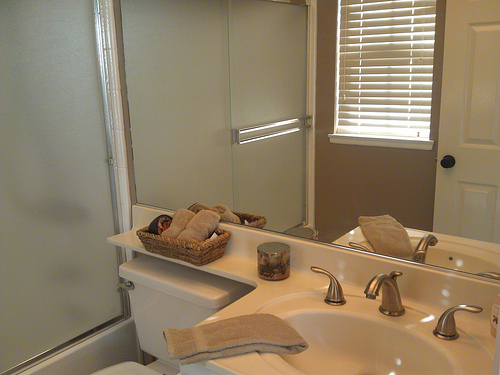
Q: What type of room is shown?
A: It is a bathroom.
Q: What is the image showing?
A: It is showing a bathroom.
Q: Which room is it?
A: It is a bathroom.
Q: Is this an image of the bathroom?
A: Yes, it is showing the bathroom.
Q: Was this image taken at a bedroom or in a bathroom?
A: It was taken at a bathroom.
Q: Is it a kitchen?
A: No, it is a bathroom.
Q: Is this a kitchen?
A: No, it is a bathroom.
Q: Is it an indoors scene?
A: Yes, it is indoors.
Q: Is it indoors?
A: Yes, it is indoors.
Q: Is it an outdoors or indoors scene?
A: It is indoors.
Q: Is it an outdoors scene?
A: No, it is indoors.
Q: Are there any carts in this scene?
A: No, there are no carts.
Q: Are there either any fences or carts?
A: No, there are no carts or fences.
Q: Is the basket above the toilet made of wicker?
A: Yes, the basket is made of wicker.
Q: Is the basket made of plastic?
A: No, the basket is made of wicker.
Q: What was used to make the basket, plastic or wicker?
A: The basket is made of wicker.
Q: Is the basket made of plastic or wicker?
A: The basket is made of wicker.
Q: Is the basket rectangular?
A: Yes, the basket is rectangular.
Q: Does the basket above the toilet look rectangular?
A: Yes, the basket is rectangular.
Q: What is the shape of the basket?
A: The basket is rectangular.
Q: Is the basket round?
A: No, the basket is rectangular.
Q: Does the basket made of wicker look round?
A: No, the basket is rectangular.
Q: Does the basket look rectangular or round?
A: The basket is rectangular.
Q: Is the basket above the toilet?
A: Yes, the basket is above the toilet.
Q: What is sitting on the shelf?
A: The basket is sitting on the shelf.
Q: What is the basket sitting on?
A: The basket is sitting on the shelf.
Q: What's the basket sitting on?
A: The basket is sitting on the shelf.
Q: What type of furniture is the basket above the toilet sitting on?
A: The basket is sitting on the shelf.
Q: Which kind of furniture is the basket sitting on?
A: The basket is sitting on the shelf.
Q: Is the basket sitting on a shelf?
A: Yes, the basket is sitting on a shelf.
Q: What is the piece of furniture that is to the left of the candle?
A: The piece of furniture is a shelf.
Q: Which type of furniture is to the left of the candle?
A: The piece of furniture is a shelf.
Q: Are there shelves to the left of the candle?
A: Yes, there is a shelf to the left of the candle.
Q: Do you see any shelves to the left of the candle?
A: Yes, there is a shelf to the left of the candle.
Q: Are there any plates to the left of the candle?
A: No, there is a shelf to the left of the candle.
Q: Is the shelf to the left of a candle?
A: Yes, the shelf is to the left of a candle.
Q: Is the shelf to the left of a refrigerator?
A: No, the shelf is to the left of a candle.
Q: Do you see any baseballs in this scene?
A: No, there are no baseballs.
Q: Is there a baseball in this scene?
A: No, there are no baseballs.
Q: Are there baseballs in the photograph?
A: No, there are no baseballs.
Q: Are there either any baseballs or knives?
A: No, there are no baseballs or knives.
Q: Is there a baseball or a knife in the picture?
A: No, there are no baseballs or knives.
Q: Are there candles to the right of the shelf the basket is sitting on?
A: Yes, there is a candle to the right of the shelf.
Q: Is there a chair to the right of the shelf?
A: No, there is a candle to the right of the shelf.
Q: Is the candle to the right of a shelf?
A: Yes, the candle is to the right of a shelf.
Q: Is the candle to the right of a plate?
A: No, the candle is to the right of a shelf.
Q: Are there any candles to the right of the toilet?
A: Yes, there is a candle to the right of the toilet.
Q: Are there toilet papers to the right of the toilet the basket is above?
A: No, there is a candle to the right of the toilet.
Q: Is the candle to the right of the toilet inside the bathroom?
A: Yes, the candle is to the right of the toilet.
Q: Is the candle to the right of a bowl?
A: No, the candle is to the right of the toilet.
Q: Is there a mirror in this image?
A: Yes, there is a mirror.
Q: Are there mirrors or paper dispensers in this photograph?
A: Yes, there is a mirror.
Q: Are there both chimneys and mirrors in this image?
A: No, there is a mirror but no chimneys.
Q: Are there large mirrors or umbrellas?
A: Yes, there is a large mirror.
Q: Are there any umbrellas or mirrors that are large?
A: Yes, the mirror is large.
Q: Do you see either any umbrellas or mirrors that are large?
A: Yes, the mirror is large.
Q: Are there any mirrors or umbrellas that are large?
A: Yes, the mirror is large.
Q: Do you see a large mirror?
A: Yes, there is a large mirror.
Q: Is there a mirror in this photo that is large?
A: Yes, there is a mirror that is large.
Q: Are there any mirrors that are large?
A: Yes, there is a mirror that is large.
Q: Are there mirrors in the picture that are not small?
A: Yes, there is a large mirror.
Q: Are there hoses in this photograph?
A: No, there are no hoses.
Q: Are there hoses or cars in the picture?
A: No, there are no hoses or cars.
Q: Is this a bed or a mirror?
A: This is a mirror.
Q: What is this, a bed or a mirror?
A: This is a mirror.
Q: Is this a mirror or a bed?
A: This is a mirror.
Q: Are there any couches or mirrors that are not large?
A: No, there is a mirror but it is large.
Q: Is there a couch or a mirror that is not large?
A: No, there is a mirror but it is large.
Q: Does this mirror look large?
A: Yes, the mirror is large.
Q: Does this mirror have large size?
A: Yes, the mirror is large.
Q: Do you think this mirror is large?
A: Yes, the mirror is large.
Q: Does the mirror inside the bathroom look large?
A: Yes, the mirror is large.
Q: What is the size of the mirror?
A: The mirror is large.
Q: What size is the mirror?
A: The mirror is large.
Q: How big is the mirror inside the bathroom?
A: The mirror is large.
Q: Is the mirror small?
A: No, the mirror is large.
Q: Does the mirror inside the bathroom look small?
A: No, the mirror is large.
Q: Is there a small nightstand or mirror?
A: No, there is a mirror but it is large.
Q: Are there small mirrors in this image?
A: No, there is a mirror but it is large.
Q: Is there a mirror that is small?
A: No, there is a mirror but it is large.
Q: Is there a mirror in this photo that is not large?
A: No, there is a mirror but it is large.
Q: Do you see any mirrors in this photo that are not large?
A: No, there is a mirror but it is large.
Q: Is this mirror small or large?
A: The mirror is large.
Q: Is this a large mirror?
A: Yes, this is a large mirror.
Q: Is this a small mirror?
A: No, this is a large mirror.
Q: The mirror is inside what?
A: The mirror is inside the bathroom.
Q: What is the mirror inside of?
A: The mirror is inside the bathroom.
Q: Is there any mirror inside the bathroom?
A: Yes, there is a mirror inside the bathroom.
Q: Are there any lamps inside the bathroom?
A: No, there is a mirror inside the bathroom.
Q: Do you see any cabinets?
A: No, there are no cabinets.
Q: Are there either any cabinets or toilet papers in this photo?
A: No, there are no cabinets or toilet papers.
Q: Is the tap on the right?
A: Yes, the tap is on the right of the image.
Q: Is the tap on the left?
A: No, the tap is on the right of the image.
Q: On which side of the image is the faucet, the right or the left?
A: The faucet is on the right of the image.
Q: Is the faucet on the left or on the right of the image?
A: The faucet is on the right of the image.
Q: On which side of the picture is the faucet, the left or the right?
A: The faucet is on the right of the image.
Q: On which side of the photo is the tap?
A: The tap is on the right of the image.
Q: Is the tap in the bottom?
A: Yes, the tap is in the bottom of the image.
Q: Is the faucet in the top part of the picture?
A: No, the faucet is in the bottom of the image.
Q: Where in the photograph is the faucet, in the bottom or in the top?
A: The faucet is in the bottom of the image.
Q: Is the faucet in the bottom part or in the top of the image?
A: The faucet is in the bottom of the image.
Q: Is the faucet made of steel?
A: Yes, the faucet is made of steel.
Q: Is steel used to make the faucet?
A: Yes, the faucet is made of steel.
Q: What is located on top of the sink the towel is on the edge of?
A: The tap is on top of the sink.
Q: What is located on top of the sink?
A: The tap is on top of the sink.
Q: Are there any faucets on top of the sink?
A: Yes, there is a faucet on top of the sink.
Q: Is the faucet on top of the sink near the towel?
A: Yes, the faucet is on top of the sink.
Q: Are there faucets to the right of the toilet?
A: Yes, there is a faucet to the right of the toilet.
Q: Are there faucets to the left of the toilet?
A: No, the faucet is to the right of the toilet.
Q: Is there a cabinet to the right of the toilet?
A: No, there is a faucet to the right of the toilet.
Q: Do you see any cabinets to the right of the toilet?
A: No, there is a faucet to the right of the toilet.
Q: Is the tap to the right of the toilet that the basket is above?
A: Yes, the tap is to the right of the toilet.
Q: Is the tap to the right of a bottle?
A: No, the tap is to the right of the toilet.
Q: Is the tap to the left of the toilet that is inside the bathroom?
A: No, the tap is to the right of the toilet.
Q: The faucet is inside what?
A: The faucet is inside the bathroom.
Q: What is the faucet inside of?
A: The faucet is inside the bathroom.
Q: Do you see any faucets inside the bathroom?
A: Yes, there is a faucet inside the bathroom.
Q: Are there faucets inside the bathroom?
A: Yes, there is a faucet inside the bathroom.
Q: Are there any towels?
A: Yes, there is a towel.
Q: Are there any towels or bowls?
A: Yes, there is a towel.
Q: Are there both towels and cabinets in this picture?
A: No, there is a towel but no cabinets.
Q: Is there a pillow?
A: No, there are no pillows.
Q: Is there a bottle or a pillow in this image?
A: No, there are no pillows or bottles.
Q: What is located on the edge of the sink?
A: The towel is on the edge of the sink.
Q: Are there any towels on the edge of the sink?
A: Yes, there is a towel on the edge of the sink.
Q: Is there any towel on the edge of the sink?
A: Yes, there is a towel on the edge of the sink.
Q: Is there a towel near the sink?
A: Yes, there is a towel near the sink.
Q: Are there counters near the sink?
A: No, there is a towel near the sink.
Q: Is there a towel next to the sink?
A: Yes, there is a towel next to the sink.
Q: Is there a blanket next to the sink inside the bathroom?
A: No, there is a towel next to the sink.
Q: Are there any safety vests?
A: No, there are no safety vests.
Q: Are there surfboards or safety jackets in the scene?
A: No, there are no safety jackets or surfboards.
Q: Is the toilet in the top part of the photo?
A: No, the toilet is in the bottom of the image.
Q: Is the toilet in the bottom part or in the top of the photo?
A: The toilet is in the bottom of the image.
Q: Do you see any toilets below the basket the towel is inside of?
A: Yes, there is a toilet below the basket.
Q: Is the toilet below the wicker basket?
A: Yes, the toilet is below the basket.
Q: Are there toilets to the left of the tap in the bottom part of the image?
A: Yes, there is a toilet to the left of the tap.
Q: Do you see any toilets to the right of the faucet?
A: No, the toilet is to the left of the faucet.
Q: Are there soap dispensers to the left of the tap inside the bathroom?
A: No, there is a toilet to the left of the tap.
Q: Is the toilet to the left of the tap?
A: Yes, the toilet is to the left of the tap.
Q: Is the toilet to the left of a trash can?
A: No, the toilet is to the left of the tap.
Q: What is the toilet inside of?
A: The toilet is inside the bathroom.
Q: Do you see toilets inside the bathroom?
A: Yes, there is a toilet inside the bathroom.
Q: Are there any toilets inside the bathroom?
A: Yes, there is a toilet inside the bathroom.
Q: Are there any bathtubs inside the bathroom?
A: No, there is a toilet inside the bathroom.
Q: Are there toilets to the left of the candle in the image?
A: Yes, there is a toilet to the left of the candle.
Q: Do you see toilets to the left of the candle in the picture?
A: Yes, there is a toilet to the left of the candle.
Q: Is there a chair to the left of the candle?
A: No, there is a toilet to the left of the candle.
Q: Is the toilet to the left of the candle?
A: Yes, the toilet is to the left of the candle.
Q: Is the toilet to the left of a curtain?
A: No, the toilet is to the left of the candle.